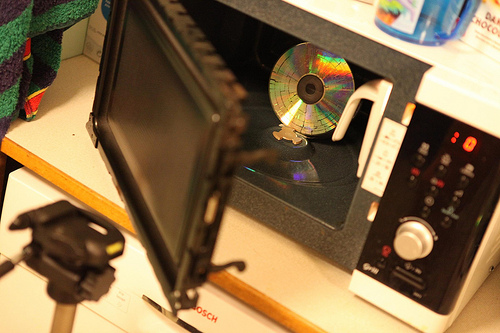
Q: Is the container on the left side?
A: No, the container is on the right of the image.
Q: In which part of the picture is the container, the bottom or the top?
A: The container is in the top of the image.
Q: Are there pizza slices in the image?
A: No, there are no pizza slices.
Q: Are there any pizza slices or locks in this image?
A: No, there are no pizza slices or locks.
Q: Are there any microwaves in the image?
A: Yes, there is a microwave.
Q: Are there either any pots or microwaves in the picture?
A: Yes, there is a microwave.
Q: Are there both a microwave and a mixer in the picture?
A: No, there is a microwave but no mixers.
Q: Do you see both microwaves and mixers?
A: No, there is a microwave but no mixers.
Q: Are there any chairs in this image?
A: No, there are no chairs.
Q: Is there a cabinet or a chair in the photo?
A: No, there are no chairs or cabinets.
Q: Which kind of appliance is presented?
A: The appliance is a microwave.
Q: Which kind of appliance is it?
A: The appliance is a microwave.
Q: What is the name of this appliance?
A: This is a microwave.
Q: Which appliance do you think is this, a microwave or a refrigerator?
A: This is a microwave.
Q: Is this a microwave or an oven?
A: This is a microwave.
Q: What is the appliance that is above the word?
A: The appliance is a microwave.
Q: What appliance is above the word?
A: The appliance is a microwave.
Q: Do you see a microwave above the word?
A: Yes, there is a microwave above the word.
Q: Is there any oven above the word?
A: No, there is a microwave above the word.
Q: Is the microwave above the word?
A: Yes, the microwave is above the word.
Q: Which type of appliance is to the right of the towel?
A: The appliance is a microwave.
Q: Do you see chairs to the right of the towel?
A: No, there is a microwave to the right of the towel.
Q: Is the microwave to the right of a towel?
A: Yes, the microwave is to the right of a towel.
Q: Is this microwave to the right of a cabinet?
A: No, the microwave is to the right of a towel.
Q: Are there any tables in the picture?
A: Yes, there is a table.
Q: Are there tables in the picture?
A: Yes, there is a table.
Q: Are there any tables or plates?
A: Yes, there is a table.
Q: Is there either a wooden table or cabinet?
A: Yes, there is a wood table.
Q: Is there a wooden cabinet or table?
A: Yes, there is a wood table.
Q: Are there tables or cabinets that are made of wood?
A: Yes, the table is made of wood.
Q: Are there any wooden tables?
A: Yes, there is a wood table.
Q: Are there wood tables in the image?
A: Yes, there is a wood table.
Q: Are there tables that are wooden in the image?
A: Yes, there is a wood table.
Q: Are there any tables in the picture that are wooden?
A: Yes, there is a table that is wooden.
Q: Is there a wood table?
A: Yes, there is a table that is made of wood.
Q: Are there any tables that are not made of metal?
A: Yes, there is a table that is made of wood.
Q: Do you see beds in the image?
A: No, there are no beds.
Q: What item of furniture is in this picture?
A: The piece of furniture is a table.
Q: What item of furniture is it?
A: The piece of furniture is a table.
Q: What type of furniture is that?
A: This is a table.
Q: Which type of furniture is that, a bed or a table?
A: This is a table.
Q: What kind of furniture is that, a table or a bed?
A: This is a table.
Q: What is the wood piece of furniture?
A: The piece of furniture is a table.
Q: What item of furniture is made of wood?
A: The piece of furniture is a table.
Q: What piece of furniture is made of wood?
A: The piece of furniture is a table.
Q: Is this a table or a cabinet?
A: This is a table.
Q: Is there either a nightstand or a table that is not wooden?
A: No, there is a table but it is wooden.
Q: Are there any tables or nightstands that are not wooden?
A: No, there is a table but it is wooden.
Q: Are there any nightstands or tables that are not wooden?
A: No, there is a table but it is wooden.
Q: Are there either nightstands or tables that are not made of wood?
A: No, there is a table but it is made of wood.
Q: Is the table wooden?
A: Yes, the table is wooden.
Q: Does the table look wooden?
A: Yes, the table is wooden.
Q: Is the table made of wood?
A: Yes, the table is made of wood.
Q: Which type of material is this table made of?
A: The table is made of wood.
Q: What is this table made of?
A: The table is made of wood.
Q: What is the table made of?
A: The table is made of wood.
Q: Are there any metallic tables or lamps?
A: No, there is a table but it is wooden.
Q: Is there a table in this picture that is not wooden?
A: No, there is a table but it is wooden.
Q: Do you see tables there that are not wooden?
A: No, there is a table but it is wooden.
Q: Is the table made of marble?
A: No, the table is made of wood.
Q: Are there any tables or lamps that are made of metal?
A: No, there is a table but it is made of wood.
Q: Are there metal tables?
A: No, there is a table but it is made of wood.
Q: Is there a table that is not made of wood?
A: No, there is a table but it is made of wood.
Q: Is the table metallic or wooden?
A: The table is wooden.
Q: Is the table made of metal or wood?
A: The table is made of wood.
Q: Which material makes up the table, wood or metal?
A: The table is made of wood.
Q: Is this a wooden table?
A: Yes, this is a wooden table.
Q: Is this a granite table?
A: No, this is a wooden table.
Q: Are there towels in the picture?
A: Yes, there is a towel.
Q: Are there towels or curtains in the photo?
A: Yes, there is a towel.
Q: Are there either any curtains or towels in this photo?
A: Yes, there is a towel.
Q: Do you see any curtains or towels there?
A: Yes, there is a towel.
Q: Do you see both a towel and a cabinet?
A: No, there is a towel but no cabinets.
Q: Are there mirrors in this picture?
A: No, there are no mirrors.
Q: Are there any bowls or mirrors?
A: No, there are no mirrors or bowls.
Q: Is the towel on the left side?
A: Yes, the towel is on the left of the image.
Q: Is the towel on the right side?
A: No, the towel is on the left of the image.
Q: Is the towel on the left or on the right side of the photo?
A: The towel is on the left of the image.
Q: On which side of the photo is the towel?
A: The towel is on the left of the image.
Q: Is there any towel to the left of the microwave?
A: Yes, there is a towel to the left of the microwave.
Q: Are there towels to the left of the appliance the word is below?
A: Yes, there is a towel to the left of the microwave.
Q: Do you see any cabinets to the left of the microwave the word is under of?
A: No, there is a towel to the left of the microwave.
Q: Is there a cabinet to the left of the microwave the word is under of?
A: No, there is a towel to the left of the microwave.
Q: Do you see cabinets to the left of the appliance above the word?
A: No, there is a towel to the left of the microwave.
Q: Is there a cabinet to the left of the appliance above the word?
A: No, there is a towel to the left of the microwave.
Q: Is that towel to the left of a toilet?
A: No, the towel is to the left of the microwave.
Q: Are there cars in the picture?
A: No, there are no cars.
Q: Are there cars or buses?
A: No, there are no cars or buses.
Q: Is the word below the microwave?
A: Yes, the word is below the microwave.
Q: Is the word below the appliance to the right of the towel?
A: Yes, the word is below the microwave.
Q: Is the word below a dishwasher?
A: No, the word is below the microwave.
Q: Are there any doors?
A: Yes, there is a door.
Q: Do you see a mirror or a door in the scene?
A: Yes, there is a door.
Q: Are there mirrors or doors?
A: Yes, there is a door.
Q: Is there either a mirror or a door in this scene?
A: Yes, there is a door.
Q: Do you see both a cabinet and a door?
A: No, there is a door but no cabinets.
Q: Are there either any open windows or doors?
A: Yes, there is an open door.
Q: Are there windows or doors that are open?
A: Yes, the door is open.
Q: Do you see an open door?
A: Yes, there is an open door.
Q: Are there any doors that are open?
A: Yes, there is a door that is open.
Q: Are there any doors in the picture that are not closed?
A: Yes, there is a open door.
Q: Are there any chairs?
A: No, there are no chairs.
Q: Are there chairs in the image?
A: No, there are no chairs.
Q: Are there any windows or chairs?
A: No, there are no chairs or windows.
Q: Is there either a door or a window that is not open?
A: No, there is a door but it is open.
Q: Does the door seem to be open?
A: Yes, the door is open.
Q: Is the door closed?
A: No, the door is open.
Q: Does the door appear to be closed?
A: No, the door is open.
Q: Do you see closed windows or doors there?
A: No, there is a door but it is open.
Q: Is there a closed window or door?
A: No, there is a door but it is open.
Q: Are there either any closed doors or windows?
A: No, there is a door but it is open.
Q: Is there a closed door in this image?
A: No, there is a door but it is open.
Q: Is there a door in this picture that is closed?
A: No, there is a door but it is open.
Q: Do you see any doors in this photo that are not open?
A: No, there is a door but it is open.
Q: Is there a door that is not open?
A: No, there is a door but it is open.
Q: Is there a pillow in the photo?
A: No, there are no pillows.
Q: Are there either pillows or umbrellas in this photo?
A: No, there are no pillows or umbrellas.